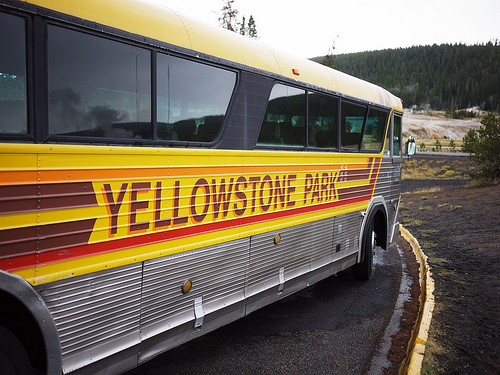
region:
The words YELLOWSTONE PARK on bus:
[86, 168, 341, 246]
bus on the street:
[0, 0, 417, 374]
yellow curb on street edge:
[396, 222, 435, 374]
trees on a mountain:
[308, 39, 498, 139]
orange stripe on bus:
[1, 155, 387, 187]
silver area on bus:
[0, 159, 402, 374]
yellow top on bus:
[1, 0, 407, 115]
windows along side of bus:
[1, 3, 403, 155]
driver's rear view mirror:
[407, 133, 417, 155]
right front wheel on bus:
[356, 221, 378, 281]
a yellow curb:
[418, 303, 436, 325]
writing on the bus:
[92, 168, 352, 240]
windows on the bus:
[51, 35, 213, 137]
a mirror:
[402, 134, 423, 159]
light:
[178, 275, 201, 293]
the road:
[275, 318, 347, 368]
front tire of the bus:
[360, 225, 391, 267]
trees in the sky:
[217, 2, 268, 33]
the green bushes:
[384, 39, 468, 86]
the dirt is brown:
[427, 193, 492, 286]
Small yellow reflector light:
[182, 280, 192, 292]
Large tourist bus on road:
[1, 1, 406, 373]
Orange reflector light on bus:
[292, 68, 297, 76]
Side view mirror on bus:
[404, 136, 415, 157]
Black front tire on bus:
[358, 216, 377, 281]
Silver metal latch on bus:
[195, 296, 205, 326]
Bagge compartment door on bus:
[139, 236, 252, 362]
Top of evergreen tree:
[248, 12, 258, 36]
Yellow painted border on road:
[401, 228, 433, 373]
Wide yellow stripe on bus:
[0, 148, 380, 283]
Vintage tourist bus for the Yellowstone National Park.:
[7, 3, 480, 370]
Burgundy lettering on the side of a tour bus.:
[67, 158, 419, 242]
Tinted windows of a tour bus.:
[5, 0, 392, 156]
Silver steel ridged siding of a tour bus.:
[95, 221, 384, 310]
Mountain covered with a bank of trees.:
[291, 22, 498, 99]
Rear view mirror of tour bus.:
[390, 132, 418, 162]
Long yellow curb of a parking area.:
[375, 215, 455, 371]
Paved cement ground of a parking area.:
[172, 286, 382, 373]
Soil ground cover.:
[419, 191, 490, 373]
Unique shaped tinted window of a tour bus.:
[151, 50, 249, 142]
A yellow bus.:
[1, 0, 418, 373]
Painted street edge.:
[396, 222, 436, 374]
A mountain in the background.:
[304, 40, 499, 106]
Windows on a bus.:
[3, 6, 403, 152]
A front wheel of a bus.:
[358, 215, 377, 277]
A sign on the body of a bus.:
[86, 168, 338, 244]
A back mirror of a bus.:
[406, 134, 418, 156]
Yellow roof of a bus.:
[19, 0, 404, 115]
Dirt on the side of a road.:
[400, 183, 498, 374]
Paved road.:
[120, 244, 406, 374]